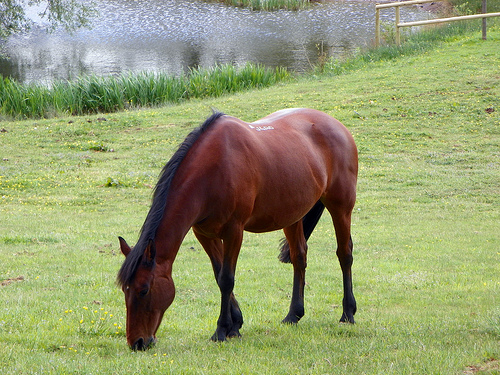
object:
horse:
[114, 105, 360, 352]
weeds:
[0, 62, 291, 121]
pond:
[0, 0, 452, 83]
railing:
[374, 0, 499, 54]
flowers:
[57, 304, 175, 369]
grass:
[0, 16, 499, 374]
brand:
[248, 123, 274, 131]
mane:
[117, 109, 222, 286]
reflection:
[12, 27, 99, 81]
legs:
[326, 180, 357, 325]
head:
[111, 235, 175, 350]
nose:
[129, 335, 151, 349]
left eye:
[139, 288, 152, 302]